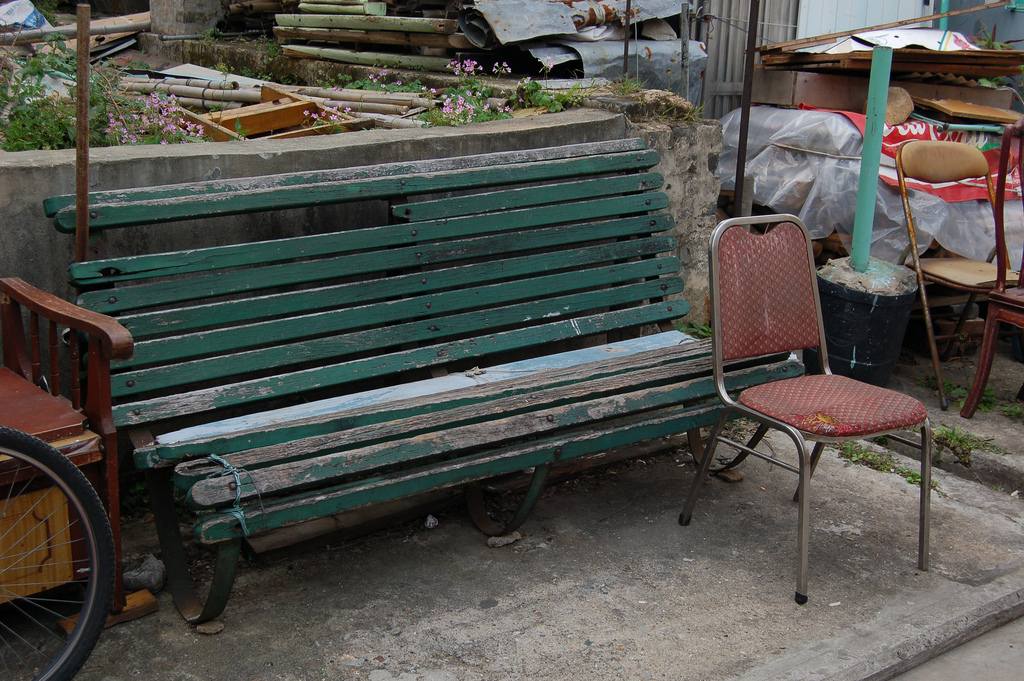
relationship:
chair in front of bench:
[676, 203, 945, 600] [25, 128, 820, 631]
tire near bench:
[6, 417, 127, 677] [25, 128, 820, 631]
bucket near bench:
[815, 249, 932, 354] [151, 162, 935, 568]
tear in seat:
[790, 408, 838, 437] [734, 363, 929, 439]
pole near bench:
[71, 4, 95, 266] [25, 128, 820, 631]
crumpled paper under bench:
[415, 507, 444, 536] [45, 131, 707, 623]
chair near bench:
[0, 267, 159, 640] [25, 128, 820, 631]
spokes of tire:
[4, 493, 74, 571] [6, 417, 127, 677]